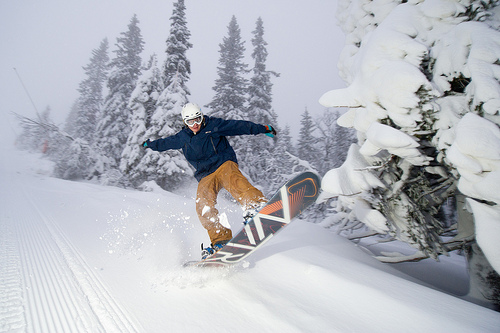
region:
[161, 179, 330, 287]
snowboard is orange black and white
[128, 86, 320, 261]
snowboarder is snowboarding down hill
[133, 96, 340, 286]
A man is on a snowboard.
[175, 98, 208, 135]
A man is wearing a white helmet.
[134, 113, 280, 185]
A man is wearing a blue top.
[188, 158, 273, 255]
A man is wearing yellow pants.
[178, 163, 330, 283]
A snowboard's colors are black, orange, and white.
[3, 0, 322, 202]
Snow-covered trees are in the background.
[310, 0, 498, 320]
A snow-covered tree is next to a snowboarder.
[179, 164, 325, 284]
A snowboard is tilted up at an angle.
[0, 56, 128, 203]
A tree has fallen onto a road.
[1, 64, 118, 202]
A fallen tree is covered in snow.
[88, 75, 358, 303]
snowboarder going down a slope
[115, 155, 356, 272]
white stripes across bottom of snowboard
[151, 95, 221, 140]
snowboarder wearing goggles and white helmet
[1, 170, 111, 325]
horizontal and vertical lines made in the snow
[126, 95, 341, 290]
snowboarder tipping up the front of board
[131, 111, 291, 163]
arms out to the sides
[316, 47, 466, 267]
heavy snow on tree branches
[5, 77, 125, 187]
tree leaning over into path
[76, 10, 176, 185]
narrow and tall evergreen trees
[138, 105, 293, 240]
blue jacket with brown pants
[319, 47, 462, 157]
Snow covered tree branches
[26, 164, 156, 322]
Tracks through the snow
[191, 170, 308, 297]
The bottom of a snow board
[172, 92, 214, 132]
A white snow helmet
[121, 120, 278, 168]
Blue snow jacket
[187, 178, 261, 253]
Brown snow pants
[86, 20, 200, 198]
Tall skinny pine trees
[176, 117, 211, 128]
Pair of white snow goggles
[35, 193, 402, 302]
Snow covered ground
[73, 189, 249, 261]
Little bits of air borne snow